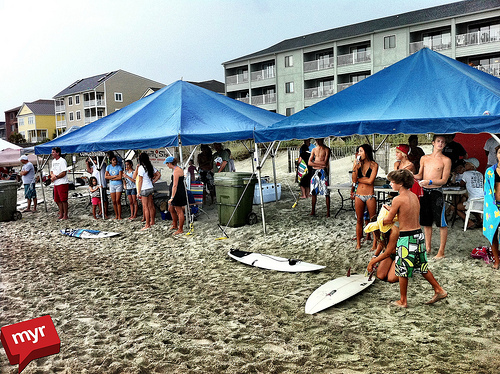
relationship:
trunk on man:
[415, 186, 449, 227] [410, 129, 465, 276]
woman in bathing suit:
[165, 152, 191, 237] [166, 167, 181, 217]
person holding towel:
[478, 142, 499, 269] [480, 165, 499, 245]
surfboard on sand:
[302, 274, 376, 314] [3, 216, 498, 370]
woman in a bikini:
[349, 143, 381, 249] [351, 161, 376, 203]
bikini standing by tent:
[351, 161, 376, 203] [249, 44, 499, 236]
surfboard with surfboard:
[58, 228, 124, 239] [58, 228, 124, 239]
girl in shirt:
[109, 152, 118, 202] [104, 162, 129, 180]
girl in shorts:
[109, 152, 118, 202] [106, 182, 126, 193]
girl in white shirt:
[131, 149, 158, 227] [135, 164, 152, 191]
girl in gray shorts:
[131, 149, 158, 227] [138, 185, 157, 196]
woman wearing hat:
[370, 208, 393, 278] [358, 208, 395, 231]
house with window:
[15, 101, 55, 143] [27, 115, 34, 126]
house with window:
[15, 101, 55, 143] [16, 117, 25, 127]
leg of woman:
[135, 194, 150, 229] [123, 147, 162, 229]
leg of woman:
[368, 250, 382, 271] [364, 125, 497, 279]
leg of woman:
[355, 195, 365, 246] [347, 124, 382, 261]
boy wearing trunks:
[378, 170, 488, 292] [401, 200, 453, 267]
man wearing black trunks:
[404, 133, 451, 260] [410, 183, 451, 232]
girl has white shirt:
[136, 150, 160, 230] [137, 165, 153, 190]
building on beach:
[230, 0, 495, 224] [12, 101, 497, 349]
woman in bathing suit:
[163, 156, 186, 235] [166, 174, 187, 207]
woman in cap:
[163, 156, 186, 235] [164, 155, 184, 165]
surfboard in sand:
[54, 220, 125, 250] [9, 150, 493, 372]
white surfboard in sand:
[227, 243, 329, 273] [188, 283, 317, 360]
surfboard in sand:
[302, 272, 376, 314] [152, 289, 239, 297]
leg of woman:
[353, 195, 365, 250] [346, 141, 376, 231]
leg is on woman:
[376, 257, 393, 281] [366, 204, 403, 269]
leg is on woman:
[355, 239, 470, 311] [331, 123, 392, 255]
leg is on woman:
[166, 204, 176, 229] [163, 153, 187, 230]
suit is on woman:
[348, 157, 378, 198] [345, 141, 390, 248]